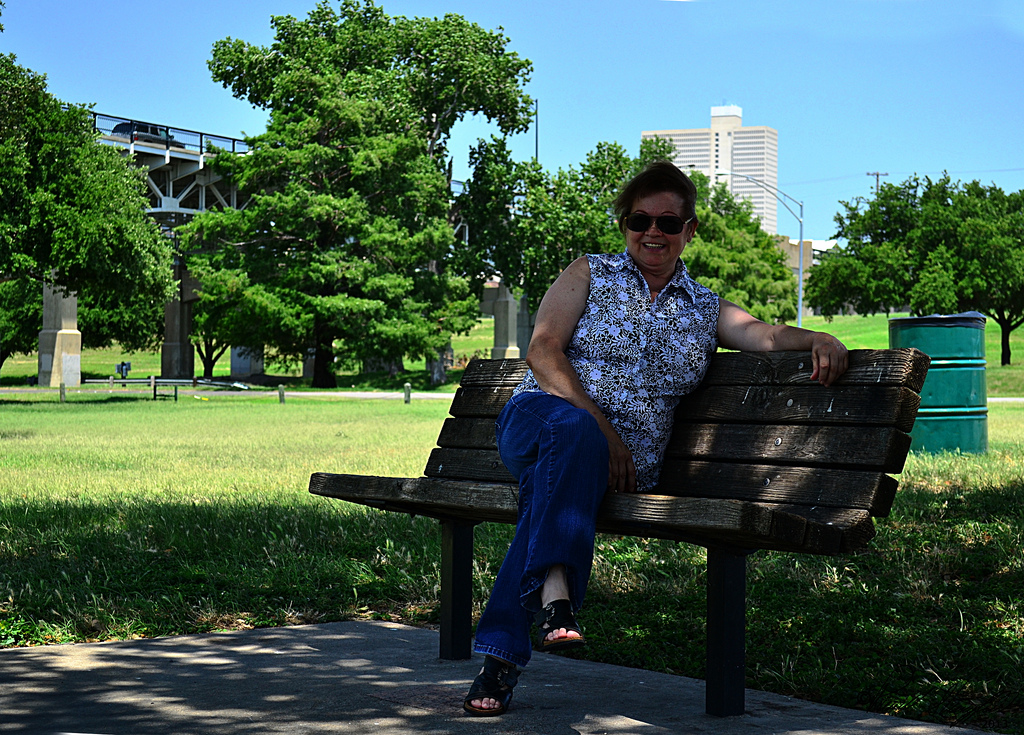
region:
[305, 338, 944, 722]
a wooden bench in the park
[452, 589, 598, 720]
a pair of black sandals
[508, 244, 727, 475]
a mingled up shirt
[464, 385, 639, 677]
pair of denium jeans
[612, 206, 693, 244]
a pair of sunglasses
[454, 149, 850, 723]
a lady resting on the bench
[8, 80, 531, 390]
a bridge for passing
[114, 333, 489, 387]
people walking in the park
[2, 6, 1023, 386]
the green trees in the park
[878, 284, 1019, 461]
trash can in the grass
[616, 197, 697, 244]
glasses on a woman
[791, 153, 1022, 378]
green trees in the grass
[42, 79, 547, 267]
bridge behind the trees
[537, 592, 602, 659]
right foot of a woman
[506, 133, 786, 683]
woman siting on brown wooden bench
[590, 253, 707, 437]
floral shirt worn by woman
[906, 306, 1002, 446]
green circular trash bin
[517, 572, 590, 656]
black sandal worn by woman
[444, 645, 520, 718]
black sandal worn by woman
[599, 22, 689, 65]
blue sky with no clouds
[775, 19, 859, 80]
blue sky with no clouds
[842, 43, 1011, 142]
blue sky with no clouds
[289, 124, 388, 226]
green leaves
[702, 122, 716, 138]
glass window on the building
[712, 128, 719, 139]
glass window on the building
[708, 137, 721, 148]
glass window on the building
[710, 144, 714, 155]
glass window on the building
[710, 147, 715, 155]
glass window on the building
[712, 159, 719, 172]
glass window on the building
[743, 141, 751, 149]
glass window on the building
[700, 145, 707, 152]
glass window on the building